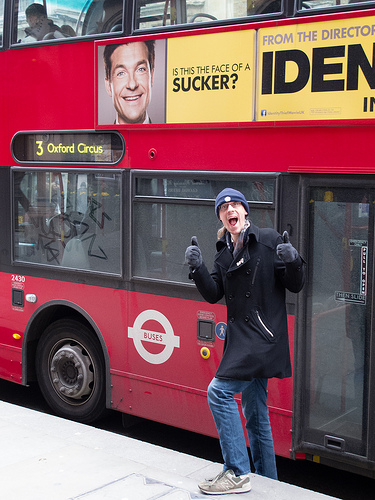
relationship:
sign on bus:
[14, 132, 123, 166] [2, 2, 373, 488]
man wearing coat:
[185, 188, 304, 495] [199, 229, 293, 375]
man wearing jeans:
[185, 188, 304, 495] [205, 375, 279, 479]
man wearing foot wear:
[185, 188, 304, 495] [196, 461, 249, 497]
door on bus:
[296, 179, 368, 458] [2, 2, 373, 488]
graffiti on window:
[16, 196, 112, 266] [13, 167, 122, 278]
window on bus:
[13, 167, 122, 278] [2, 2, 373, 488]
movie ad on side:
[99, 22, 374, 121] [2, 40, 373, 177]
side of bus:
[2, 40, 373, 177] [2, 2, 373, 488]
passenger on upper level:
[23, 4, 60, 40] [1, 3, 373, 50]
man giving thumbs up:
[185, 188, 304, 495] [178, 227, 298, 264]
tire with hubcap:
[35, 318, 105, 416] [50, 342, 89, 394]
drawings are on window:
[28, 199, 118, 267] [13, 167, 122, 278]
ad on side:
[170, 27, 372, 106] [2, 40, 373, 177]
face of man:
[220, 201, 245, 231] [185, 188, 304, 495]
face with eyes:
[220, 201, 245, 231] [213, 201, 242, 213]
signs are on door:
[331, 235, 370, 324] [296, 179, 368, 458]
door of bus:
[296, 179, 368, 458] [2, 2, 373, 488]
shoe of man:
[196, 456, 254, 499] [185, 188, 304, 495]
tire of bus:
[35, 318, 105, 416] [2, 2, 373, 488]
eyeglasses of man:
[215, 199, 251, 214] [185, 188, 304, 495]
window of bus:
[13, 167, 122, 278] [2, 2, 373, 488]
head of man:
[216, 190, 244, 233] [185, 188, 304, 495]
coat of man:
[199, 229, 293, 375] [185, 188, 304, 495]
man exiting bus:
[185, 188, 304, 495] [2, 2, 373, 488]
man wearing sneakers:
[185, 188, 304, 495] [196, 456, 254, 499]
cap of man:
[214, 188, 242, 208] [185, 188, 304, 495]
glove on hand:
[187, 236, 205, 272] [183, 234, 209, 275]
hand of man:
[183, 234, 209, 275] [185, 188, 304, 495]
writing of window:
[18, 174, 112, 270] [13, 167, 122, 278]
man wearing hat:
[185, 188, 304, 495] [210, 185, 246, 217]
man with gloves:
[185, 188, 304, 495] [177, 227, 306, 279]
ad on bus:
[170, 27, 372, 106] [2, 2, 373, 488]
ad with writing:
[170, 27, 372, 106] [257, 30, 375, 98]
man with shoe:
[185, 188, 304, 495] [196, 456, 254, 499]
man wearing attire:
[185, 188, 304, 495] [191, 231, 298, 481]